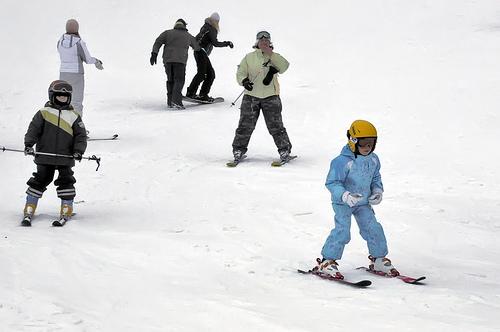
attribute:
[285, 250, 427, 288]
skis — child's pair 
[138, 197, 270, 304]
snow — slope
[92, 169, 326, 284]
snow — white 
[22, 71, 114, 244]
snow suit — black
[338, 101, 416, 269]
kids — Skiing 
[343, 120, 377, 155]
helmet — Yellow 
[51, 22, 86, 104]
person —  gray trim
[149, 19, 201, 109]
person — Standing 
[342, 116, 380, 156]
helmet — Yellow 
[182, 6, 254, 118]
snowboarder — Female 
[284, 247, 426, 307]
skis — Red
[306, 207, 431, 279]
pants — Blue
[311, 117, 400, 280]
girl — young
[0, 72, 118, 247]
child — Skiing 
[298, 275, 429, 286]
skis — white ski 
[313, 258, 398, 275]
ski boots —  red 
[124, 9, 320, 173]
people — Skiing 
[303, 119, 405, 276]
boy — young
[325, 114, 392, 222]
helmet — yellow/orange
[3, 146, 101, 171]
ski pole — ski 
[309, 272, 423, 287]
skis — young girls 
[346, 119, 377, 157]
yellow helmet —  girls 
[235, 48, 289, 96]
jacket — Light colored 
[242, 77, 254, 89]
glove — Black 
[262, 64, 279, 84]
glove — Black 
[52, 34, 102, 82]
jacket — white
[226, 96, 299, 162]
pants —  camouflage 